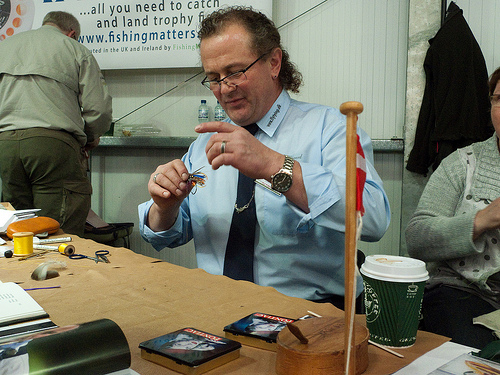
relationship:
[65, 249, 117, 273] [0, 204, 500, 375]
scissors on table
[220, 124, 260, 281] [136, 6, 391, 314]
tie on person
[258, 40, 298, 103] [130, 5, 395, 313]
ear of man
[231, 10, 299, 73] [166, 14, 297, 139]
hair on mans head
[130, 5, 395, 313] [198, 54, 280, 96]
man wearing glasses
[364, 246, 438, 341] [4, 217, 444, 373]
cup on table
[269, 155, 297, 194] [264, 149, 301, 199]
watch on wrist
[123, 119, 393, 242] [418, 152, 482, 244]
arm on person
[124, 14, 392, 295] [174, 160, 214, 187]
man holding bait